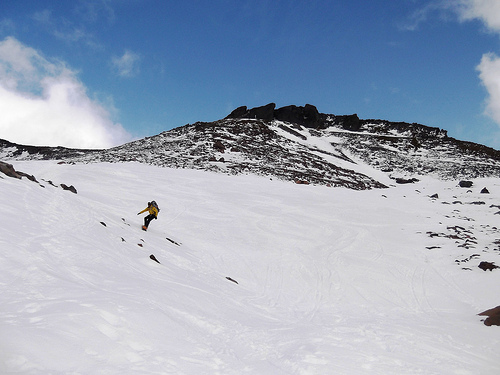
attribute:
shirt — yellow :
[139, 206, 161, 218]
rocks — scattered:
[429, 213, 496, 293]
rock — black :
[1, 156, 21, 179]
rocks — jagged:
[222, 103, 447, 142]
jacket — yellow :
[135, 205, 161, 219]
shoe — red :
[139, 221, 146, 233]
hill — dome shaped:
[117, 104, 497, 182]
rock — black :
[58, 178, 82, 199]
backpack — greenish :
[150, 201, 158, 211]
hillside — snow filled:
[4, 143, 499, 373]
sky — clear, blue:
[0, 0, 498, 152]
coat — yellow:
[118, 178, 190, 262]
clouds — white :
[0, 30, 143, 181]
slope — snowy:
[1, 145, 497, 373]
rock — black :
[144, 251, 166, 269]